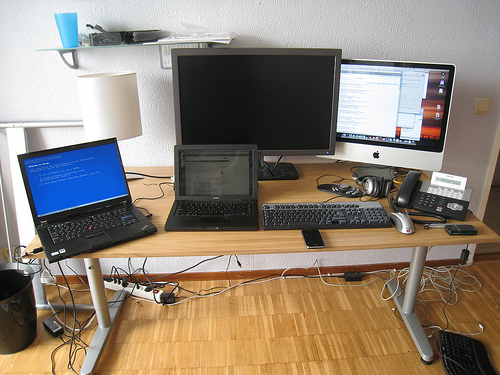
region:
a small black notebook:
[175, 145, 260, 237]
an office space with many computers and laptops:
[16, 2, 490, 367]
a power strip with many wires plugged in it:
[106, 263, 192, 308]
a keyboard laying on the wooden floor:
[428, 293, 498, 373]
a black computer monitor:
[171, 45, 341, 151]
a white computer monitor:
[346, 55, 443, 175]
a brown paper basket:
[2, 251, 52, 369]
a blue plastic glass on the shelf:
[48, 7, 84, 52]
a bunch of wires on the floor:
[315, 265, 496, 296]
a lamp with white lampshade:
[67, 67, 161, 157]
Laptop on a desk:
[16, 144, 178, 272]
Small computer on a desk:
[154, 143, 267, 240]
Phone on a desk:
[289, 223, 326, 253]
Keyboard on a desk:
[258, 195, 423, 230]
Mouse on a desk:
[393, 204, 436, 274]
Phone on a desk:
[401, 150, 483, 232]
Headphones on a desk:
[336, 168, 421, 209]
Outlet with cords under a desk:
[103, 267, 203, 304]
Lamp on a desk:
[65, 66, 171, 186]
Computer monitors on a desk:
[155, 38, 451, 169]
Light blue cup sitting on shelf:
[39, 8, 88, 60]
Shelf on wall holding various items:
[41, 8, 241, 57]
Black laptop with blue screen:
[8, 140, 160, 233]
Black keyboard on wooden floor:
[426, 328, 499, 372]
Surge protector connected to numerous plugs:
[99, 269, 185, 313]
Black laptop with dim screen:
[174, 145, 264, 230]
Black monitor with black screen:
[161, 44, 337, 159]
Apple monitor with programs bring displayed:
[336, 50, 443, 174]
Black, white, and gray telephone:
[393, 168, 473, 220]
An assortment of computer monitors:
[18, 30, 456, 214]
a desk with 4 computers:
[9, 2, 496, 324]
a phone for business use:
[392, 165, 466, 233]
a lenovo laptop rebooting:
[14, 136, 155, 268]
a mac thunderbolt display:
[352, 55, 473, 175]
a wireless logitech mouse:
[392, 211, 423, 239]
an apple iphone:
[287, 222, 337, 259]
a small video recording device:
[434, 219, 485, 239]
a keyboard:
[262, 184, 397, 237]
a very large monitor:
[158, 36, 338, 176]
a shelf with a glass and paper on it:
[29, 9, 255, 54]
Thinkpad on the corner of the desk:
[11, 135, 159, 262]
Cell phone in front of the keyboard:
[300, 225, 323, 250]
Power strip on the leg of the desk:
[101, 264, 173, 303]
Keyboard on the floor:
[434, 327, 493, 373]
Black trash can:
[1, 257, 43, 349]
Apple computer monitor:
[326, 55, 451, 162]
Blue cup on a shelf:
[51, 4, 83, 51]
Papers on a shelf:
[156, 22, 237, 43]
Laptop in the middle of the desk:
[165, 140, 259, 232]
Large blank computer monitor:
[170, 43, 341, 155]